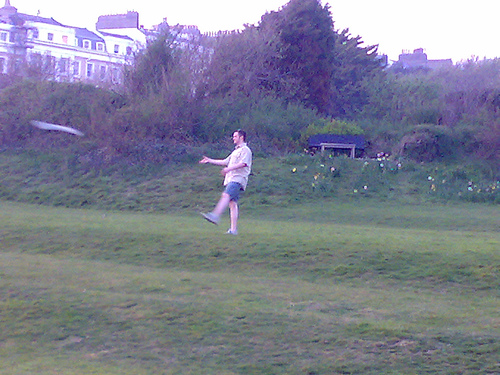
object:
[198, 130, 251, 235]
man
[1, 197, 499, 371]
field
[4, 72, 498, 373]
grass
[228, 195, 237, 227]
leg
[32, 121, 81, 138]
object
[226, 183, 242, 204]
shorts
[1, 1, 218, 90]
building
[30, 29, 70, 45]
windows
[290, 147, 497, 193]
flowers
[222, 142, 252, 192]
shirt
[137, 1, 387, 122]
trees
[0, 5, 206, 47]
roof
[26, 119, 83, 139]
frisbee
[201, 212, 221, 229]
shoes